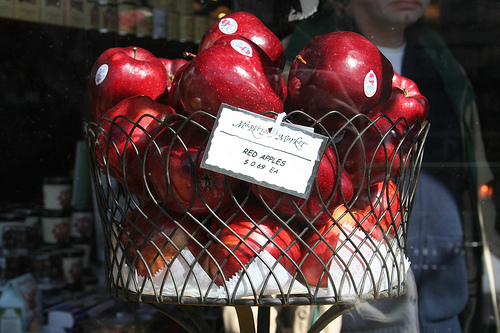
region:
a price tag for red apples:
[195, 96, 330, 203]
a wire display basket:
[64, 103, 436, 316]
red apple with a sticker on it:
[83, 37, 168, 134]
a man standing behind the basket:
[258, 1, 497, 331]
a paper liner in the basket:
[101, 230, 416, 305]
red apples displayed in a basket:
[67, 8, 437, 318]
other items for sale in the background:
[7, 175, 101, 332]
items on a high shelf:
[3, 2, 226, 47]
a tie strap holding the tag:
[262, 102, 292, 142]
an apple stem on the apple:
[126, 37, 141, 67]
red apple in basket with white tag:
[285, 29, 363, 123]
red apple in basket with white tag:
[181, 36, 262, 101]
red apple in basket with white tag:
[206, 13, 264, 37]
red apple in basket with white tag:
[82, 40, 164, 102]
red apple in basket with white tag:
[119, 139, 186, 187]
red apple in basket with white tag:
[91, 117, 175, 169]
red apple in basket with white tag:
[116, 203, 181, 268]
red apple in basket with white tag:
[212, 220, 279, 284]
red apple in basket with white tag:
[305, 214, 355, 291]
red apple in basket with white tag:
[386, 80, 437, 180]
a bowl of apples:
[36, 4, 480, 331]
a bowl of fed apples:
[79, 11, 471, 306]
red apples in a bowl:
[79, 19, 419, 331]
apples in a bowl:
[46, 13, 481, 332]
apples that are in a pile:
[67, 16, 422, 330]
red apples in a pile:
[72, 4, 457, 330]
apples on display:
[67, 18, 424, 330]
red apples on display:
[77, 8, 447, 323]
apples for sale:
[87, 16, 431, 330]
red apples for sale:
[66, 7, 429, 298]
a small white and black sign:
[205, 99, 320, 200]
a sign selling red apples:
[191, 86, 348, 211]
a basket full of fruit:
[61, 8, 444, 315]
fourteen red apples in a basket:
[80, 0, 420, 298]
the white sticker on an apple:
[227, 39, 257, 61]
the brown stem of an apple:
[125, 44, 147, 65]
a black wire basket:
[92, 109, 432, 312]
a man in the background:
[296, 0, 495, 331]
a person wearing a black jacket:
[290, 22, 498, 330]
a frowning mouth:
[352, 0, 438, 25]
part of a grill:
[374, 223, 394, 234]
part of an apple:
[194, 168, 219, 178]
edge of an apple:
[255, 290, 272, 296]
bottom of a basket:
[244, 274, 270, 302]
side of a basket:
[176, 250, 200, 285]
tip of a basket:
[261, 296, 264, 304]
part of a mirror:
[443, 214, 457, 240]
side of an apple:
[198, 34, 225, 101]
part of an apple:
[320, 102, 335, 132]